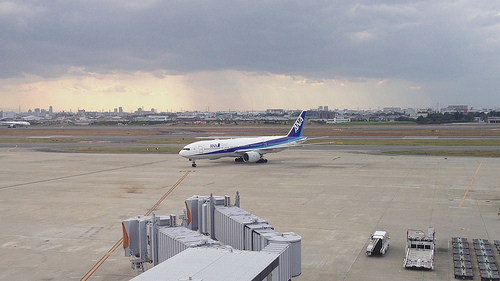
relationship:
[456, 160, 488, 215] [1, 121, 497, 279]
line on ground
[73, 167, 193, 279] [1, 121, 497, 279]
line on ground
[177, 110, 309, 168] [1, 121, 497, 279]
plane on ground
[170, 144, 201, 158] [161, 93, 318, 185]
windows on plane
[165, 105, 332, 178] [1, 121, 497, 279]
plane on ground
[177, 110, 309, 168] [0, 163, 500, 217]
plane on concrete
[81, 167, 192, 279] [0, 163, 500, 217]
line painted on concrete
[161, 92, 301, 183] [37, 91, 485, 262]
airplane on ground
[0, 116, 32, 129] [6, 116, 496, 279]
airplane on runway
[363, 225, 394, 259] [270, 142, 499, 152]
vehicle on runway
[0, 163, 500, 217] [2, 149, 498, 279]
concrete on ground